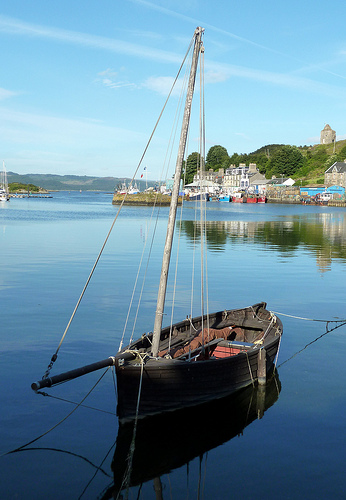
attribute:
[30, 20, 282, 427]
ship — filled, wooden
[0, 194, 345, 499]
bay — flat, murky, reflective, calm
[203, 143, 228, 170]
tree — green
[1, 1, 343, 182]
sky — misty, cloudy, cloudless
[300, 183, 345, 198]
building — blue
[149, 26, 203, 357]
mast — straighy